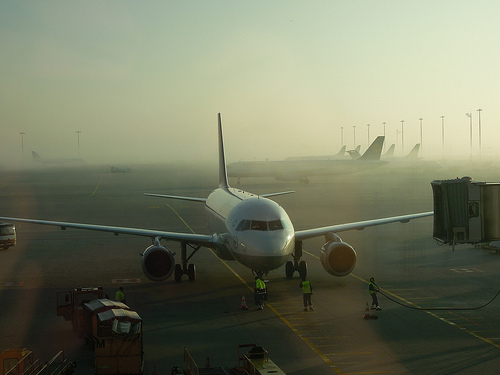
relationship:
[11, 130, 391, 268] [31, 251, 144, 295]
plane on runway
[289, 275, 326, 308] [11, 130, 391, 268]
worker in front plane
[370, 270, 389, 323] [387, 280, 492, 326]
man dragging hose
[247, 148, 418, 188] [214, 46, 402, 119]
planes in background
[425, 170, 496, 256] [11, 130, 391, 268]
walkway by plane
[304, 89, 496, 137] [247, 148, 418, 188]
lights behind planes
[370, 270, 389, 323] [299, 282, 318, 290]
man in vest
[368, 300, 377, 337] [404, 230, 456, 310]
cone on ground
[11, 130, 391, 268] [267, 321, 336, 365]
plane between line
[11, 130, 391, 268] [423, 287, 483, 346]
plane between line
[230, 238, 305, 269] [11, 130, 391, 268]
nose of plane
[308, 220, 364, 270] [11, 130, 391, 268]
engine of plane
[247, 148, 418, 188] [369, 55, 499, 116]
planes in mist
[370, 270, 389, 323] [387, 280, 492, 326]
man holding hose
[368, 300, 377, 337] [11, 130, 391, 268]
cone in front plane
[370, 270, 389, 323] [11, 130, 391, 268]
man in front plane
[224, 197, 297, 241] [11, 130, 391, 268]
windows in front plane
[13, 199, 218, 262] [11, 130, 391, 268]
wing of plane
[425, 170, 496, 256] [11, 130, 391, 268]
walkway from plane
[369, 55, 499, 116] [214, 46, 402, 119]
mist in background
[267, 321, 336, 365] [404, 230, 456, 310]
line on ground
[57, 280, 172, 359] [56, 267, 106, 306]
wagon for container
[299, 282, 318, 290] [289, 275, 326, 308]
vest on worker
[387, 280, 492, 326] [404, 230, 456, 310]
hose on ground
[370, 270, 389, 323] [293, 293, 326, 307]
man in pants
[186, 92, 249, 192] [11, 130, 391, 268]
tail on plane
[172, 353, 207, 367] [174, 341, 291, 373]
back of truck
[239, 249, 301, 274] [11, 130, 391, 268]
bottom of plane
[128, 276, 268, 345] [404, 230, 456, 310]
shadow on ground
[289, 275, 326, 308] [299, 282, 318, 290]
worker in vest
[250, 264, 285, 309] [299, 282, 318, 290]
person in vest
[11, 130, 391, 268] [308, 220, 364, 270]
plane has engine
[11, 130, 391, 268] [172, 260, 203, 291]
plane with landing gear